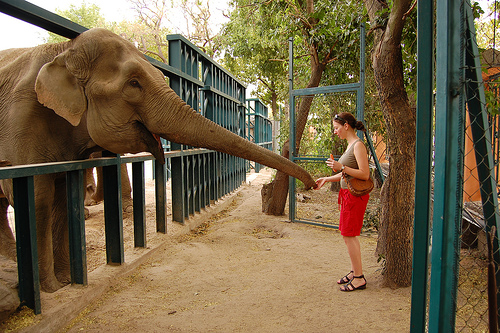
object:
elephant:
[0, 25, 320, 322]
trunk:
[140, 89, 320, 191]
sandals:
[338, 274, 368, 293]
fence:
[451, 0, 499, 333]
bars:
[165, 33, 248, 225]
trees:
[337, 1, 423, 292]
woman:
[312, 111, 371, 292]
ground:
[54, 191, 413, 331]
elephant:
[81, 151, 136, 221]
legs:
[117, 153, 134, 218]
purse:
[340, 170, 375, 197]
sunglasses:
[333, 114, 348, 124]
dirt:
[80, 224, 133, 272]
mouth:
[131, 118, 180, 165]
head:
[32, 23, 318, 191]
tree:
[205, 0, 373, 217]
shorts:
[337, 187, 370, 237]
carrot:
[329, 153, 338, 173]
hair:
[331, 111, 368, 132]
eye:
[125, 76, 146, 91]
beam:
[0, 0, 207, 88]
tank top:
[347, 139, 368, 151]